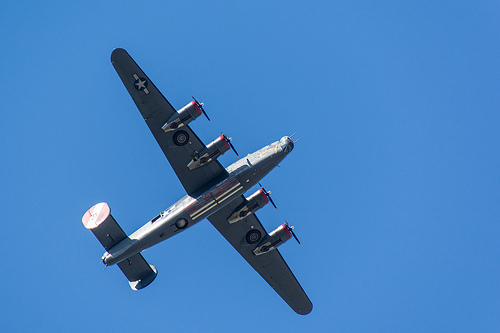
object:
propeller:
[191, 95, 211, 122]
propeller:
[257, 182, 277, 210]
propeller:
[284, 219, 301, 245]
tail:
[81, 202, 158, 290]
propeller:
[220, 132, 239, 157]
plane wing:
[110, 47, 225, 195]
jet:
[82, 46, 314, 316]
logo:
[185, 175, 240, 215]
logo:
[132, 73, 150, 94]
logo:
[173, 130, 189, 146]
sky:
[1, 1, 494, 330]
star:
[135, 79, 147, 90]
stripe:
[190, 183, 243, 221]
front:
[270, 132, 299, 160]